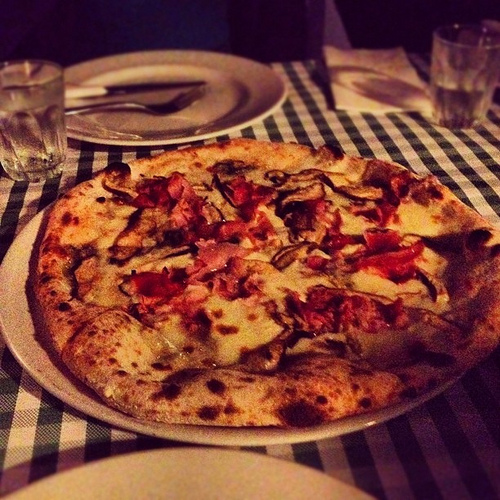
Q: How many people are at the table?
A: Three.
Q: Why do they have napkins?
A: To clean themselves.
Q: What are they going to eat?
A: Pizza.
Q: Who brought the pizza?
A: The waiter.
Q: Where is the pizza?
A: In the middle of the table.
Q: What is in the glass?
A: Water.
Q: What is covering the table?
A: A table cloth.